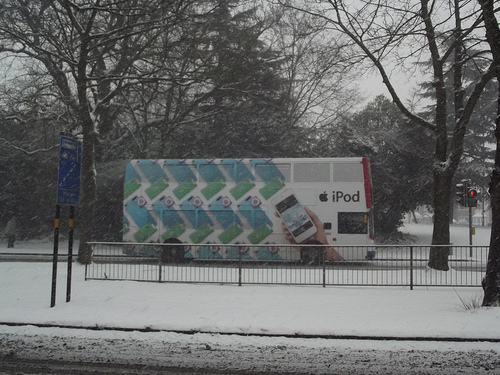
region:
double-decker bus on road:
[93, 100, 438, 300]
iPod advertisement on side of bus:
[276, 173, 368, 249]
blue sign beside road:
[36, 122, 97, 294]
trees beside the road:
[373, 65, 498, 318]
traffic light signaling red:
[456, 176, 486, 226]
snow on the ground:
[13, 244, 493, 344]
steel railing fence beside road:
[64, 235, 498, 290]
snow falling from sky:
[18, 78, 269, 270]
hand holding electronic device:
[267, 186, 327, 256]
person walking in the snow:
[2, 201, 29, 261]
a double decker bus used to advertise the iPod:
[121, 155, 371, 261]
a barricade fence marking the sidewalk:
[81, 240, 487, 290]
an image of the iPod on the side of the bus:
[271, 188, 316, 243]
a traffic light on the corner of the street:
[456, 177, 479, 258]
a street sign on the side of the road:
[48, 134, 82, 307]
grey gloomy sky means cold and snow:
[1, 1, 499, 145]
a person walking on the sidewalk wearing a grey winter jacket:
[3, 213, 19, 249]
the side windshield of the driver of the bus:
[338, 211, 370, 234]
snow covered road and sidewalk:
[1, 260, 499, 365]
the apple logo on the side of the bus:
[318, 190, 330, 202]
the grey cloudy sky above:
[5, 3, 499, 118]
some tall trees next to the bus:
[2, 1, 297, 152]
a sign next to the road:
[56, 139, 80, 302]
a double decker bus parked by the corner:
[123, 157, 374, 268]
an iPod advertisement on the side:
[269, 187, 321, 242]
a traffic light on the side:
[454, 174, 484, 255]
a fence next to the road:
[81, 236, 498, 290]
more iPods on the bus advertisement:
[121, 157, 278, 262]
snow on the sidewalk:
[8, 265, 498, 355]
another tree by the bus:
[373, 64, 471, 267]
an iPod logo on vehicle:
[315, 190, 367, 207]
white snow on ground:
[205, 287, 410, 332]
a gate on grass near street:
[95, 242, 484, 287]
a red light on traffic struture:
[457, 173, 489, 259]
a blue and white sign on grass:
[52, 130, 93, 215]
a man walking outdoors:
[6, 210, 26, 255]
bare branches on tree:
[48, 48, 174, 117]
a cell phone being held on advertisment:
[257, 192, 338, 259]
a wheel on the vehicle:
[155, 237, 188, 267]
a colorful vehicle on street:
[115, 150, 375, 265]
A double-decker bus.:
[116, 147, 371, 262]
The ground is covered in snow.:
[0, 255, 495, 340]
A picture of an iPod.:
[270, 181, 316, 241]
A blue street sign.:
[40, 125, 85, 320]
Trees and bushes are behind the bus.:
[15, 5, 426, 250]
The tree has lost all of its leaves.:
[340, 0, 490, 272]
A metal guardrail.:
[75, 230, 490, 291]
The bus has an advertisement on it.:
[115, 156, 385, 261]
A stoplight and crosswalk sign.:
[455, 175, 480, 260]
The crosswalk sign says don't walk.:
[463, 183, 481, 203]